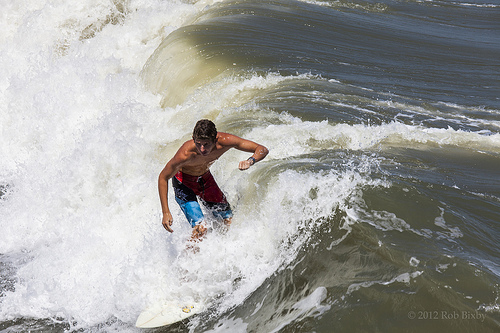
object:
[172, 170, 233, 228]
shorts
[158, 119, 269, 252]
person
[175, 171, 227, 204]
red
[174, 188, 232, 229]
blue shorts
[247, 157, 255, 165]
band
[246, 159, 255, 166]
wrist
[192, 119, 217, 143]
brown hair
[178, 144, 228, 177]
chested